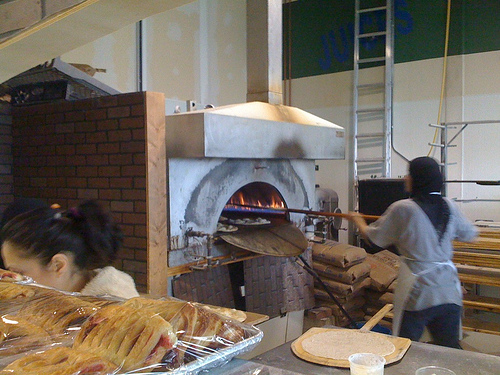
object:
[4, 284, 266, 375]
wrap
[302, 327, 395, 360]
dough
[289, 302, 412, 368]
tray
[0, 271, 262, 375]
pastries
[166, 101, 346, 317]
oven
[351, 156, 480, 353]
woman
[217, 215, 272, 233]
pizza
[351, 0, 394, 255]
ladder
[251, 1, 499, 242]
wall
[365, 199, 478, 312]
shirt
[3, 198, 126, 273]
hair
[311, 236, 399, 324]
flower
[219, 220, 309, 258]
door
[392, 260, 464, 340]
apron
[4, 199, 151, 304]
woman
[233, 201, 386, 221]
spatula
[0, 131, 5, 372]
left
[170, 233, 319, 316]
brick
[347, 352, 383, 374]
cup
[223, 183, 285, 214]
fire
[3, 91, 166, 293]
brick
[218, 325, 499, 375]
countertop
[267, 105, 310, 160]
mark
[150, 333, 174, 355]
berry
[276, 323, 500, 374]
counter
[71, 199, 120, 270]
ponytail